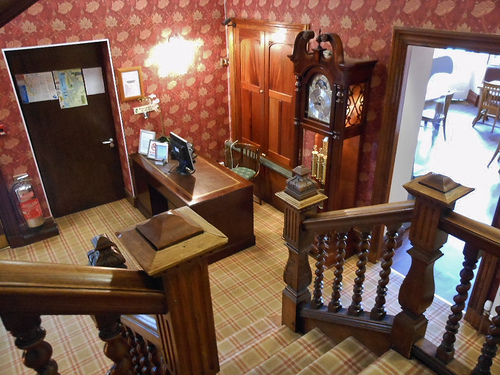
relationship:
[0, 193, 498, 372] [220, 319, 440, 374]
rug on stairs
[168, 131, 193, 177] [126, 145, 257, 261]
monitor sitting on desk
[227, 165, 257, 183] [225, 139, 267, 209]
cushion sitting on chair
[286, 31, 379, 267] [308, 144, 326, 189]
grandfather clock has gears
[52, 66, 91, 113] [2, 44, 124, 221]
map hanging on door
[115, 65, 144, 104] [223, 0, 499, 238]
frame hanging on wall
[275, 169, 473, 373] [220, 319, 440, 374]
stair rail beside stairs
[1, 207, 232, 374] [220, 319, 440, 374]
stair rail beside stairs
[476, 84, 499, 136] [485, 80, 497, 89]
chair sitting at table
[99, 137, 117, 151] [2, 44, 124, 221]
door knob on door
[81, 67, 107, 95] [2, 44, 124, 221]
paper hanging on door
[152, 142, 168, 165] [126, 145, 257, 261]
frame sitting on desk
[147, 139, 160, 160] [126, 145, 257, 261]
frame sitting on desk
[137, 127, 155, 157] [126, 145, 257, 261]
frame sitting on desk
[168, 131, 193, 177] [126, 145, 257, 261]
monitor on desk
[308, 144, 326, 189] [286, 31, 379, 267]
gears are inside of grandfather clock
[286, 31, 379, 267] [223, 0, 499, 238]
grandfather clock against wall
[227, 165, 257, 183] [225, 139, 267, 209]
cushion in chair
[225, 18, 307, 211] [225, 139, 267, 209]
doors are behind chair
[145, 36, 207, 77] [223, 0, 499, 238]
light reflectig on wall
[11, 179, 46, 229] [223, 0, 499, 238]
fire extinguisher against wall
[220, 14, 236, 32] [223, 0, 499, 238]
security camera hanging on wall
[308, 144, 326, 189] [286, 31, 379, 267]
chimes are inside of grandfather clock